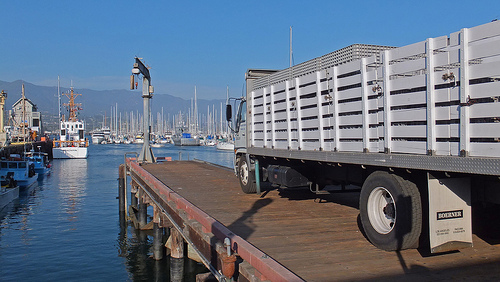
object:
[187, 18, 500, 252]
truck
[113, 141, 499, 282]
pier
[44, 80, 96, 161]
boat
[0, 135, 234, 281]
bay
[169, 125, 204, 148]
yachts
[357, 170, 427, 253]
tire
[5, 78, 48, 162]
building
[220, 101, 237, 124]
mirror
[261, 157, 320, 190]
gas tank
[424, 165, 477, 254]
mud flap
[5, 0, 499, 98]
sky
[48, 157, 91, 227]
reflection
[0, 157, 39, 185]
boats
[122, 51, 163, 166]
crane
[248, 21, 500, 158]
paneling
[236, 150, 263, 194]
tire